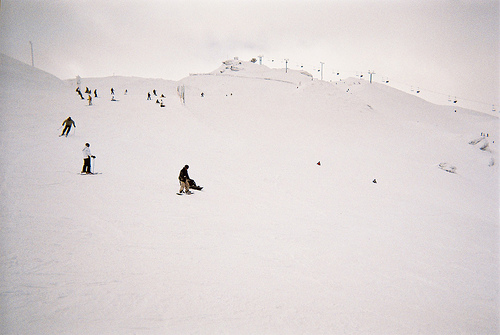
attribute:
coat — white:
[79, 144, 94, 161]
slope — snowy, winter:
[0, 59, 498, 335]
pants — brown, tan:
[178, 178, 190, 190]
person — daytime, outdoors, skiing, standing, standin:
[60, 116, 77, 136]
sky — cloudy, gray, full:
[2, 2, 499, 118]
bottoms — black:
[80, 157, 93, 173]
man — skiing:
[87, 95, 94, 107]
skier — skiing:
[146, 92, 152, 100]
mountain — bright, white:
[1, 55, 498, 333]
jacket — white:
[178, 167, 189, 184]